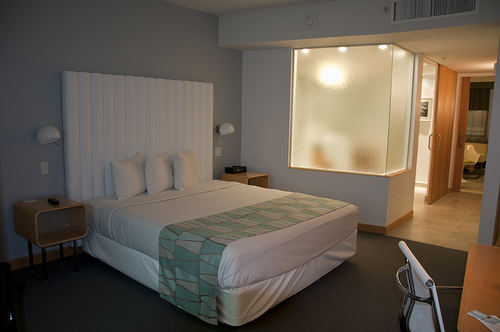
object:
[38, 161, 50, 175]
lightswitch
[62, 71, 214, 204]
headboard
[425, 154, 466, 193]
ground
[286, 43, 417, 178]
window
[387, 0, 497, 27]
vent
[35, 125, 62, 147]
bulb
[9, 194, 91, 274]
night table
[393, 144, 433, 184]
ground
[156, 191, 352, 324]
blanket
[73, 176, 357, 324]
bed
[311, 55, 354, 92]
light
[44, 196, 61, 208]
splashing water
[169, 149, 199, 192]
pillow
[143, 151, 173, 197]
pillow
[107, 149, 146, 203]
pillow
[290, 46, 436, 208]
bathroom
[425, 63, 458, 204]
door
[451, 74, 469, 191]
door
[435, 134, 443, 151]
handle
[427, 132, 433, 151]
handle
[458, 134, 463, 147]
handle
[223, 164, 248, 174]
stuff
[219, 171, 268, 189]
table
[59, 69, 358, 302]
modern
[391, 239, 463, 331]
chair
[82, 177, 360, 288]
mattress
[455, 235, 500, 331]
desk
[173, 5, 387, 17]
ceiling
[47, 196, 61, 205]
control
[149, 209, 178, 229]
part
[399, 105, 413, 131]
part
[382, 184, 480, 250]
floor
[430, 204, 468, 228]
part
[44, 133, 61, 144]
part